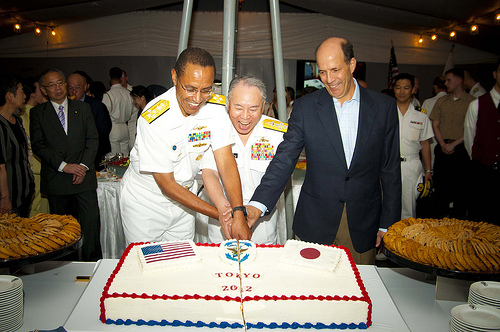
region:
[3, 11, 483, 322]
lots of people at a party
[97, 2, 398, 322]
three men cutting a large cake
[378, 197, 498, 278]
a platter of cookies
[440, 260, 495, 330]
stacks of white plates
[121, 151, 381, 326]
three people holding the knife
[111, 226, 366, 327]
cake reads Tokyo 2012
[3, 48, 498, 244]
lots of people standing behind the three men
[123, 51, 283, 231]
two men are military uniform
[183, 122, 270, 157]
two men have lots of awards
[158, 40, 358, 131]
all three men are smiling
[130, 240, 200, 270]
American flag on cake.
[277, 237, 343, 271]
Japanese flag on cake.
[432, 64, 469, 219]
Solider wearing brown shirt.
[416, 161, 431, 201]
Military hat being held by solider.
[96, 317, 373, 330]
Blue line of icing on cake.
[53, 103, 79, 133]
Lilac colored tie with blue stripes.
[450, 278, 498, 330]
Two stack of white plates side by side.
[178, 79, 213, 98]
Eyeglasses being worn by man cutting cake.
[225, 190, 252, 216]
Black watch being worn by man cutting cake.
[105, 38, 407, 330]
Three men cutting into a sheet cake.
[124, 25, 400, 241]
the men cutting the cake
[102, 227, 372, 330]
the cake is red white and blue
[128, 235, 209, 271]
the american flag on the cake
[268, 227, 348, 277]
the japanese flag on the cake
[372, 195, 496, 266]
the tray of cookies on the table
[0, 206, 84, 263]
the tray of cookies on the table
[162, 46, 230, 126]
the man wearing glasses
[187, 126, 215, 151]
the medals on the chest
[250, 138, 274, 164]
the medals on the chest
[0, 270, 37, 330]
the stack of plates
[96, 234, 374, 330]
Japan and America decorated cake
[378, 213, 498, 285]
Large plate of cookies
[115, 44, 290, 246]
Two men in military uniforms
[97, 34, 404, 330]
Three men slicing a cake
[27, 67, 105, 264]
Man with glasses in suit and tie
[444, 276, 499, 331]
Two stacks of plates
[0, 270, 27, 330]
Stack of white plates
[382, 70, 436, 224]
Man in military uniform holding hat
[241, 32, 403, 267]
Man in blue suit jacket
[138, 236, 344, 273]
American and Japanese flags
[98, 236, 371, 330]
a big cake on a table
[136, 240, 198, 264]
an American flag on a cake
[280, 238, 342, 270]
a Japanese flag on a cake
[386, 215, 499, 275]
a selection of cookies on a tray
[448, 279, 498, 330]
a stack of small white plates on a table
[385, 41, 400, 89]
an American flag on a pole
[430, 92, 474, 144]
man wearing a brown shirt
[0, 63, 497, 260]
a crowd of people gathered in a room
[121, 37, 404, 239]
three men about to cut a cake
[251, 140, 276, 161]
colorful decorations on a uniform